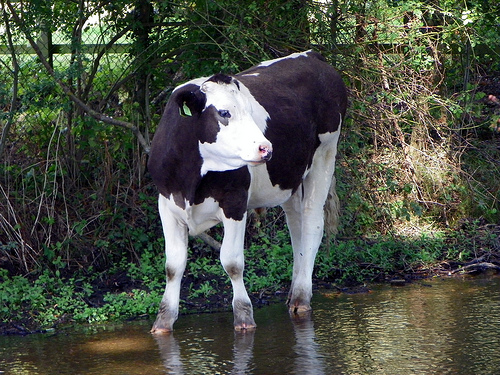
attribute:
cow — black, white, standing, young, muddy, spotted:
[139, 39, 393, 333]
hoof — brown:
[217, 301, 274, 330]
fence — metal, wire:
[1, 20, 153, 125]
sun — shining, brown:
[357, 283, 436, 370]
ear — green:
[158, 81, 208, 132]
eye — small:
[203, 98, 257, 143]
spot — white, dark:
[238, 50, 317, 86]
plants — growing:
[352, 42, 486, 240]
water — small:
[323, 301, 429, 362]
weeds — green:
[375, 122, 452, 202]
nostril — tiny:
[244, 127, 282, 155]